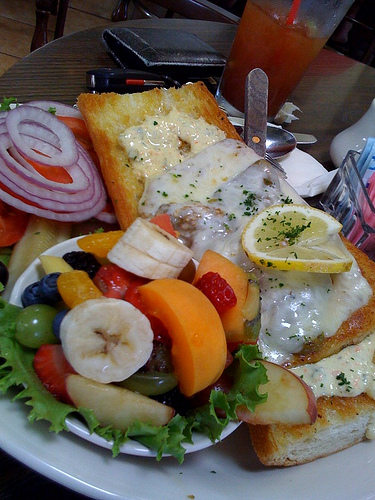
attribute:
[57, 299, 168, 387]
banana slice — round, here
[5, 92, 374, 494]
plate — white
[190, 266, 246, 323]
berry — here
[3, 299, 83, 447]
lettuce — green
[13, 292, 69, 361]
grape — green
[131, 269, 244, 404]
orange slice — here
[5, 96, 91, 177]
onion slice — here, red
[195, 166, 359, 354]
cheese — melted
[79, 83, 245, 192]
bread — garlic, toasted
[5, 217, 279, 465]
fruit salad — fresh